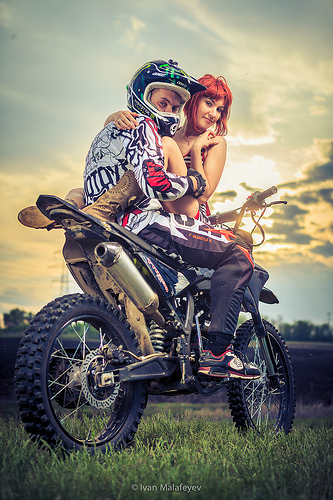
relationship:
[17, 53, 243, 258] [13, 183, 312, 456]
couple on motorcycle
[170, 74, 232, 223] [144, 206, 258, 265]
woman sits lap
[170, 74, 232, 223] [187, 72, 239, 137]
girl has red hair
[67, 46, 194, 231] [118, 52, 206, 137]
man wears helmet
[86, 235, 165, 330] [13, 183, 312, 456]
exhaust of motorcycle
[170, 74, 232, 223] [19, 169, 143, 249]
woman wears boots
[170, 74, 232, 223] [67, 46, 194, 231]
woman intertwined with man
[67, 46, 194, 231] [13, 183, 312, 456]
man on motorcycle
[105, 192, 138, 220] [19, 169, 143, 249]
straps on boots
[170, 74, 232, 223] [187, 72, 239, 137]
woman chin length hair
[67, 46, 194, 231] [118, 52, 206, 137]
man wearing helmet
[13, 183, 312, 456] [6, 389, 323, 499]
motorcycle parked on grass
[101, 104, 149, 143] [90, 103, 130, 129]
hand on shoulder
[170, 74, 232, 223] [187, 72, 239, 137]
woman with hair red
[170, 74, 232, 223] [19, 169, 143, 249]
woman hs boots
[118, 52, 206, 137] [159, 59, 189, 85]
helmet with green writing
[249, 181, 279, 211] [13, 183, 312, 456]
handle front of motorcycle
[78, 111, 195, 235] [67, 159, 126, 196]
jacket with black writing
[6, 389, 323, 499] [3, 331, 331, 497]
grass on ground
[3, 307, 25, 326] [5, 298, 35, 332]
leaves on tree